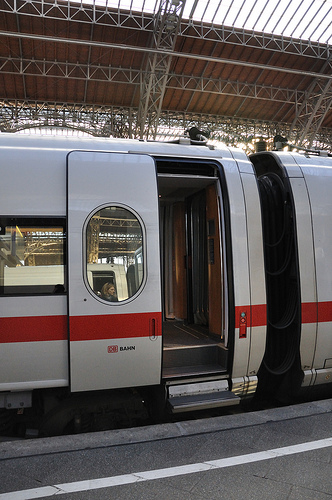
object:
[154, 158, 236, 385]
door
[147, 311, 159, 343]
handle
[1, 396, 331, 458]
curb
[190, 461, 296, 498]
cracks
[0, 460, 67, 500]
cracks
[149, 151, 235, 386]
doorway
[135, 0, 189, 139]
cables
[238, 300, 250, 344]
buttons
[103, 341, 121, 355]
symbol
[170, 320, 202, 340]
marks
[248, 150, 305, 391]
hose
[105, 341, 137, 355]
logo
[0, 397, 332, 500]
concrete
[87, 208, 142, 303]
reflection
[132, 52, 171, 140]
metal beam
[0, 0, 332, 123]
ceiling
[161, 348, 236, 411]
steps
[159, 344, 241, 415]
stairs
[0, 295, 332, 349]
stripe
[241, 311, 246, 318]
green light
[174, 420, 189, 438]
marks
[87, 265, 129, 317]
woman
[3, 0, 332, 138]
bridge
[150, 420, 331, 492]
paint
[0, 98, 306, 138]
metal rafters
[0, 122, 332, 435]
car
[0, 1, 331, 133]
roof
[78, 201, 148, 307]
window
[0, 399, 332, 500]
ground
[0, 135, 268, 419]
train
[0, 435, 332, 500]
line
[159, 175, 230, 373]
hallway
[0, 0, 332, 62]
truss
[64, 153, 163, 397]
door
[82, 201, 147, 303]
glass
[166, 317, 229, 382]
floor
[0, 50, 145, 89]
truss